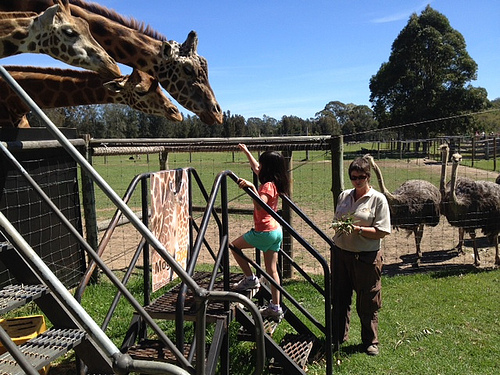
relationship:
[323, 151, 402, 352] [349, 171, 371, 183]
woman wears sunglasses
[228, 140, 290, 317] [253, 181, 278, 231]
girl wears shirt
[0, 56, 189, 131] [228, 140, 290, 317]
giraffe look girl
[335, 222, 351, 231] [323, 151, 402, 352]
leaves on woman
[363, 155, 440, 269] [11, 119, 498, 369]
ostrich in pen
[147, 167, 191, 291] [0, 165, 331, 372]
sign on gate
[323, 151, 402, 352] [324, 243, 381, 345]
woman wearing pants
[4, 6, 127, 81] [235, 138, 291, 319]
giraffe looking at girl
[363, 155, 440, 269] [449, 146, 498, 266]
ostrich next to ostrich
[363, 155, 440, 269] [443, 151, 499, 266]
ostrich next to ostrich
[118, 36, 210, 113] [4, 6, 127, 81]
giraffe next to giraffe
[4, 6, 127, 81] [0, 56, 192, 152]
giraffe next to giraffe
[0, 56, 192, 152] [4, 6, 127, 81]
giraffe next to giraffe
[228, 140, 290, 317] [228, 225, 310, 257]
girl wearing shorts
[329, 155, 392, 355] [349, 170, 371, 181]
person wearing sunglasses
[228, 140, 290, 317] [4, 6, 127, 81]
girl feeding giraffe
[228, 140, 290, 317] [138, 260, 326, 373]
girl standing on stairs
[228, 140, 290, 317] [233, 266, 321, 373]
girl standing on stairs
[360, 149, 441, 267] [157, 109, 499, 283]
bird behind fence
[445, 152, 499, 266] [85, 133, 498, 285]
bird behind fence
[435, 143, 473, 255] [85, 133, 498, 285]
bird behind fence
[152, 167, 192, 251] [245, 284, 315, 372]
image over stairs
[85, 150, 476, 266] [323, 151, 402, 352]
fence behind woman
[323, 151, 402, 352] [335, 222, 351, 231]
woman holding leaves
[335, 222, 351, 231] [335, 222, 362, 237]
leaves in hand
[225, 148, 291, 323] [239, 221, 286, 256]
woman wearing shorts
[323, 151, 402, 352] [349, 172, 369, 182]
woman wearing sunglasses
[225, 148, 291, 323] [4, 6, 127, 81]
woman reaching for giraffe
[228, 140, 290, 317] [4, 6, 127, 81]
girl looking at giraffe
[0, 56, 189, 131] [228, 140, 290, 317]
giraffe looking at girl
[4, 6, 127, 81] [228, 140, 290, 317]
giraffe looking at girl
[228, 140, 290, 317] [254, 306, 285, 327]
girl wearing shoe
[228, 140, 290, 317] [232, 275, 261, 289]
girl wearing shoe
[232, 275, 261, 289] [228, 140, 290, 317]
shoe on girl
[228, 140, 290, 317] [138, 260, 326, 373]
girl climbing stairs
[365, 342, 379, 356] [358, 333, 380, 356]
foot wearing shoe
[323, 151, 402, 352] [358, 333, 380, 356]
woman wearing shoe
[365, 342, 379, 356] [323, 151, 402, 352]
foot belonging to woman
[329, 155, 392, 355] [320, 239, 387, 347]
person wearing pants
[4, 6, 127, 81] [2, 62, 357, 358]
giraffe overlooking stairs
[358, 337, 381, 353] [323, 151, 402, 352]
shoe on woman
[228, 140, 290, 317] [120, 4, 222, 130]
girl about to feed giraffe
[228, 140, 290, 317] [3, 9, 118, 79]
girl about to feed giraffe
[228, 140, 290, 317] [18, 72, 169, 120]
girl about to feed giraffe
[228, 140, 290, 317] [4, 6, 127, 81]
girl about to feed giraffe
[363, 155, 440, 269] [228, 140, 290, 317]
ostrich looking at girl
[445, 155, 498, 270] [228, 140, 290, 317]
ostrich looking at girl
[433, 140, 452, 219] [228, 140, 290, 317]
ostrich looking at girl